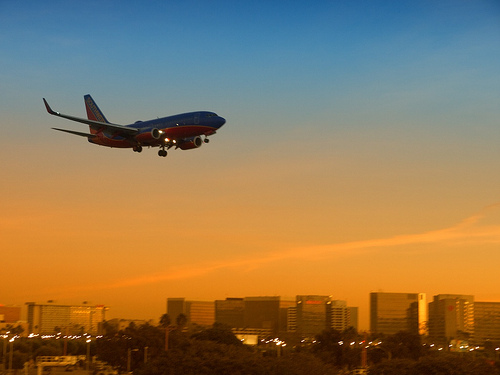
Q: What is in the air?
A: A plane.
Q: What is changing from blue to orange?
A: The sky.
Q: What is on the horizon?
A: Skyscrapers.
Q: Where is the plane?
A: In the air.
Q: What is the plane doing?
A: Flying.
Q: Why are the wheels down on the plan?
A: It's about to land.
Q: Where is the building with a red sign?
A: Middle.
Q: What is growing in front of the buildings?
A: Trees.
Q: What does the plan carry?
A: Passengers.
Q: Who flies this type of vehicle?
A: Pilot.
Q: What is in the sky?
A: Plane.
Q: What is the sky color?
A: Blue and yellow.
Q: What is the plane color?
A: Red and blue.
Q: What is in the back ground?
A: Sky scrapper.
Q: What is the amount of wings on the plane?
A: Three wings.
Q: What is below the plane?
A: Trees.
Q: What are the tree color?
A: Green.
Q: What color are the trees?
A: Green.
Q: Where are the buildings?
A: Below the plane.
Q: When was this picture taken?
A: Sunset.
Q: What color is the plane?
A: Red & blue.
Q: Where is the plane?
A: Mid-air.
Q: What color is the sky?
A: Blue and orange.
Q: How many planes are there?
A: One.